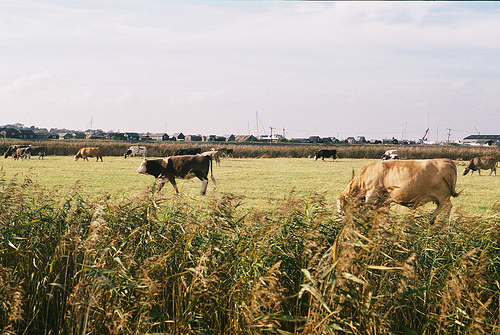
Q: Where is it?
A: This is at the field.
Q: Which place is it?
A: It is a field.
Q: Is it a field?
A: Yes, it is a field.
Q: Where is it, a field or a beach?
A: It is a field.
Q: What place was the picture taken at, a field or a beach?
A: It was taken at a field.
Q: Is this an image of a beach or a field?
A: It is showing a field.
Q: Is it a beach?
A: No, it is a field.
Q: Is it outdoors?
A: Yes, it is outdoors.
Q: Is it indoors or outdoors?
A: It is outdoors.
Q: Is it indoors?
A: No, it is outdoors.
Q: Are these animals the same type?
A: Yes, all the animals are cows.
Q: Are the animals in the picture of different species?
A: No, all the animals are cows.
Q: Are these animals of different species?
A: No, all the animals are cows.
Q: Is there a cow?
A: Yes, there is a cow.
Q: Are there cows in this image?
A: Yes, there is a cow.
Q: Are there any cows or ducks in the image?
A: Yes, there is a cow.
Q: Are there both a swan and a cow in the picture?
A: No, there is a cow but no swans.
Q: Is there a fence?
A: No, there are no fences.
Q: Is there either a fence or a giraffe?
A: No, there are no fences or giraffes.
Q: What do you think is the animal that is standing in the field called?
A: The animal is a cow.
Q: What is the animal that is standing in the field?
A: The animal is a cow.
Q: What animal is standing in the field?
A: The animal is a cow.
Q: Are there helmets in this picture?
A: No, there are no helmets.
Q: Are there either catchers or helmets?
A: No, there are no helmets or catchers.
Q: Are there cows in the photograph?
A: Yes, there is a cow.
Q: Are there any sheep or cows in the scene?
A: Yes, there is a cow.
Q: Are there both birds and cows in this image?
A: No, there is a cow but no birds.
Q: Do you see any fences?
A: No, there are no fences.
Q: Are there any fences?
A: No, there are no fences.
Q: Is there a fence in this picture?
A: No, there are no fences.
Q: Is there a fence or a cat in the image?
A: No, there are no fences or cats.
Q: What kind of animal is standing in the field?
A: The animal is a cow.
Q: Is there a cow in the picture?
A: Yes, there is a cow.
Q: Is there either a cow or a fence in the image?
A: Yes, there is a cow.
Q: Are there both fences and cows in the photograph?
A: No, there is a cow but no fences.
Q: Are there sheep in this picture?
A: No, there are no sheep.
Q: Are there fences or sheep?
A: No, there are no sheep or fences.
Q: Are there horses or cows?
A: Yes, there is a cow.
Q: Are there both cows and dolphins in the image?
A: No, there is a cow but no dolphins.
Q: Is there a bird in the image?
A: No, there are no birds.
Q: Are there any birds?
A: No, there are no birds.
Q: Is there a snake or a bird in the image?
A: No, there are no birds or snakes.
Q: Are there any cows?
A: Yes, there is a cow.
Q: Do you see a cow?
A: Yes, there is a cow.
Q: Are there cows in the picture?
A: Yes, there is a cow.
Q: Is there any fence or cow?
A: Yes, there is a cow.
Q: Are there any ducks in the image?
A: No, there are no ducks.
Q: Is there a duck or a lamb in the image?
A: No, there are no ducks or lambs.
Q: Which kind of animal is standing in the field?
A: The animal is a cow.